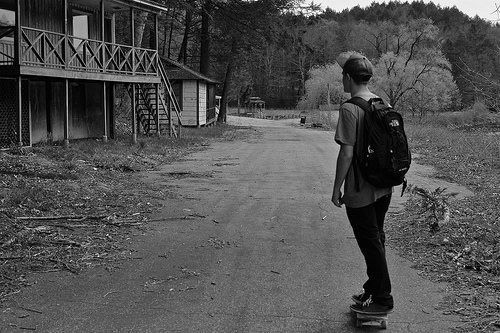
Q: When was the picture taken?
A: Daytime.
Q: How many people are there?
A: One.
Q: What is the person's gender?
A: Male.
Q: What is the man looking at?
A: A building.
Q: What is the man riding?
A: A skateboard.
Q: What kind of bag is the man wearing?
A: A backpack.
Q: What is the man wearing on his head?
A: A cap.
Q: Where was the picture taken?
A: Road.